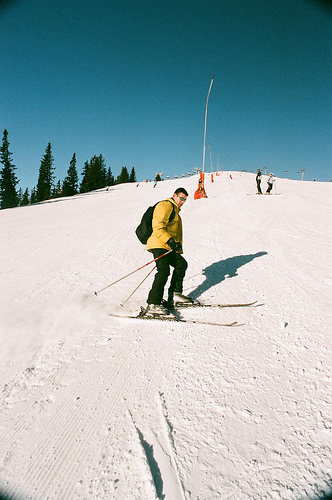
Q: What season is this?
A: Winter.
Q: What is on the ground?
A: Snow.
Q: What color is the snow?
A: White.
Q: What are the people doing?
A: Skiing.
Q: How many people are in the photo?
A: Four.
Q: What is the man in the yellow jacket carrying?
A: Backpack.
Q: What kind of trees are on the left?
A: Pine trees.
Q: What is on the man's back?
A: A backpack.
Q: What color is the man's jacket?
A: Yellow.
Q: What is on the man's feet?
A: Skis.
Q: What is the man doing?
A: Skiing.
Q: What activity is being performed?
A: Skiing.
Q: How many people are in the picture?
A: 3.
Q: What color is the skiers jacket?
A: Yellow.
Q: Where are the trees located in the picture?
A: Left side.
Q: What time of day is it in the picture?
A: Daytime.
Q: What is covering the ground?
A: Snow.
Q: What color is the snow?
A: White.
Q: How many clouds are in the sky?
A: None.